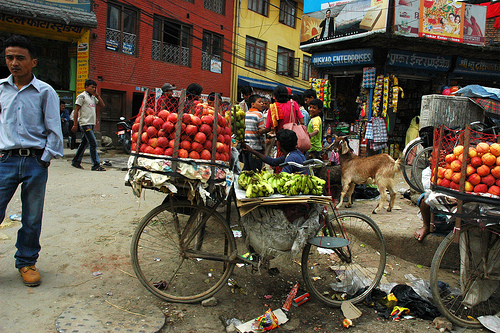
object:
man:
[0, 34, 67, 291]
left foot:
[9, 255, 46, 289]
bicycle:
[125, 144, 392, 309]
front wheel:
[297, 210, 391, 309]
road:
[0, 153, 235, 332]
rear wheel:
[126, 196, 242, 305]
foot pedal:
[265, 264, 283, 278]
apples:
[193, 132, 208, 144]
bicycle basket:
[119, 83, 244, 198]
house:
[90, 0, 232, 97]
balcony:
[146, 37, 194, 69]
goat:
[330, 138, 404, 215]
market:
[1, 1, 500, 333]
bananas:
[243, 182, 254, 198]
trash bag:
[384, 281, 442, 327]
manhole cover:
[49, 285, 173, 332]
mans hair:
[0, 34, 38, 59]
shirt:
[0, 73, 66, 170]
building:
[235, 1, 315, 108]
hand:
[32, 157, 49, 181]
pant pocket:
[32, 152, 55, 168]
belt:
[0, 147, 50, 157]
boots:
[11, 258, 46, 289]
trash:
[228, 305, 292, 333]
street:
[0, 224, 500, 332]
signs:
[295, 0, 389, 49]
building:
[300, 0, 500, 155]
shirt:
[73, 90, 101, 128]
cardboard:
[235, 194, 334, 217]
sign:
[415, 0, 467, 44]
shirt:
[240, 107, 269, 151]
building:
[88, 0, 236, 152]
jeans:
[0, 144, 55, 269]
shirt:
[262, 149, 315, 178]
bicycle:
[119, 85, 393, 310]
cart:
[430, 120, 498, 202]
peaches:
[467, 172, 482, 186]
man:
[67, 78, 108, 173]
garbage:
[325, 260, 455, 325]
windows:
[240, 33, 271, 72]